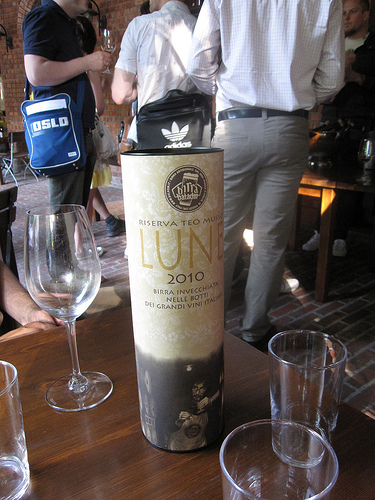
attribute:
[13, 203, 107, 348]
glass — empty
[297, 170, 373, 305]
table — wooden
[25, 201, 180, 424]
glasses — empty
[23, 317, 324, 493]
table — brown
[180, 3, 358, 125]
shirt — button down, checkered, white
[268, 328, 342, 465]
glass — empty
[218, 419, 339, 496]
glass — empty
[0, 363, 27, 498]
glass — empty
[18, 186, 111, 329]
glass — empty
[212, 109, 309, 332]
pants — grey, gray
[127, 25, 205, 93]
shirt — white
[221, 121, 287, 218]
trouser — gray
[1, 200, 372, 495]
glasses — empty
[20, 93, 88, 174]
bag — blue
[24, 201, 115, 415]
glass — empty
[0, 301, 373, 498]
table — brown, wood, wooden